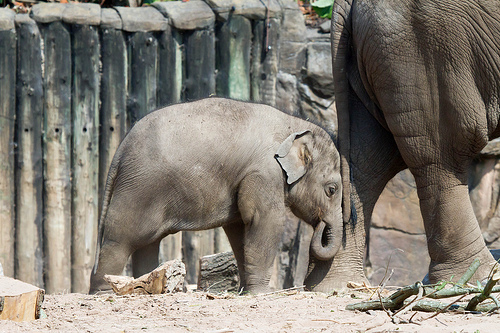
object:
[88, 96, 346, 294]
elephant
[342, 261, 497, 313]
branches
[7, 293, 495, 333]
ground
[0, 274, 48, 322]
wood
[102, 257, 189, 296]
wood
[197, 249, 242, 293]
wood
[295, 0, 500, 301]
elephant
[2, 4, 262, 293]
fence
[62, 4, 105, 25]
rock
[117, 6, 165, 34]
rock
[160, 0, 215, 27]
rock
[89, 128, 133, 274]
tail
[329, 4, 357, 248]
tail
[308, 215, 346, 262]
trunk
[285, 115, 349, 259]
head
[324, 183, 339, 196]
eye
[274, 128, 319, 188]
ear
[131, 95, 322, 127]
back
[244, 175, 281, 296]
leg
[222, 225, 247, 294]
leg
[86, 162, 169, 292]
leg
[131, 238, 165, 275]
leg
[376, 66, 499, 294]
leg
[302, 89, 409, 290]
leg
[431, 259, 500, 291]
foot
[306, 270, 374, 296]
foot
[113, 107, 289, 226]
skin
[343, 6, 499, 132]
skin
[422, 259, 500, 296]
branch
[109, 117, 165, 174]
backside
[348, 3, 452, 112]
backside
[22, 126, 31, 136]
holes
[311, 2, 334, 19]
leaf